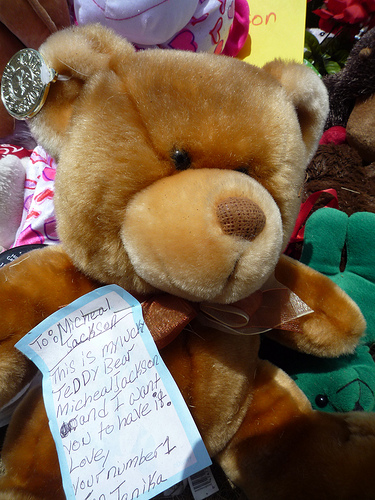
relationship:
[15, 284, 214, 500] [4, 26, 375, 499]
note on teddy bear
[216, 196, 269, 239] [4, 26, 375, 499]
nose on teddy bear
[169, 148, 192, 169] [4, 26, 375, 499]
eye on teddy bear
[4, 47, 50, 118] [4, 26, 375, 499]
gold coin on teddy bear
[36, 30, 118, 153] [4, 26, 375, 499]
ear of teddy bear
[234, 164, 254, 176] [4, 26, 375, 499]
eye of teddy bear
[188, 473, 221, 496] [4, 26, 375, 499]
bar code on teddy bear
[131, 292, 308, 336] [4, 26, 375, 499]
ribbon on teddy bear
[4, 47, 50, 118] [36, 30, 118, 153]
medallion attached to bears ear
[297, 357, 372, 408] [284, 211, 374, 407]
face of green bear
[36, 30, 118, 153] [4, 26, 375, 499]
ear on teddy bear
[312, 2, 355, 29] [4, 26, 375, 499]
flower behind teddy bear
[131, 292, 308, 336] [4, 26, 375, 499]
tie on teddy bear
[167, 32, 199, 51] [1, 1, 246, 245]
heart on teddy bear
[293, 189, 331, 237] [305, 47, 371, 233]
red ribbon on teddy bear